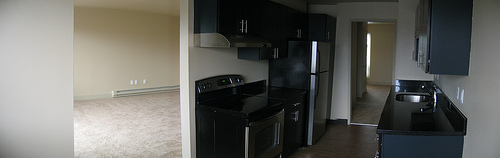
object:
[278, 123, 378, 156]
floor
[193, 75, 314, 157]
black stove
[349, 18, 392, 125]
hallway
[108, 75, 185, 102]
baseboard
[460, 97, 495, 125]
ground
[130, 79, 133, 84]
outlet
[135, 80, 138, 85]
outlet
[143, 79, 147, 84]
outlet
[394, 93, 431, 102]
sink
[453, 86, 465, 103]
outlet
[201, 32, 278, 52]
vent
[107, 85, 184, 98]
heater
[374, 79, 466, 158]
counter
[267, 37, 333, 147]
fridge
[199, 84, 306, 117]
stovetop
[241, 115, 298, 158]
oven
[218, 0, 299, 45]
cabinets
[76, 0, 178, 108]
wall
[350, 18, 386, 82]
doorway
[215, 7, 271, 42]
doors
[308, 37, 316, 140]
handles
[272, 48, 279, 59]
handles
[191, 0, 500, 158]
kitchen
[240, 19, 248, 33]
handles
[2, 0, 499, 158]
room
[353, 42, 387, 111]
hallway